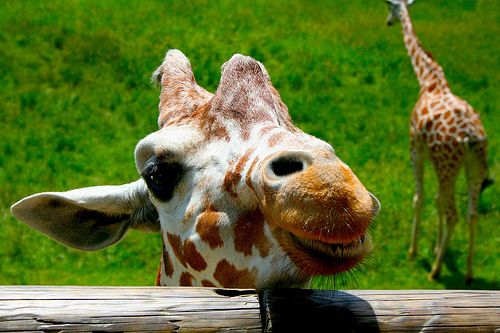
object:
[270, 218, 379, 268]
mouth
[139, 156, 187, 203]
eye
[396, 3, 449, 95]
neck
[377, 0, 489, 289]
giraffe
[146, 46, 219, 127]
horns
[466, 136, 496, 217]
tail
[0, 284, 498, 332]
beam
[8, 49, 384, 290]
giraffe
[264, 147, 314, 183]
nostril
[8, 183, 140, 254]
ear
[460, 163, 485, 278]
leg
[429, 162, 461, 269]
leg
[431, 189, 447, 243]
leg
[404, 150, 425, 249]
leg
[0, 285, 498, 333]
fence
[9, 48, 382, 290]
head